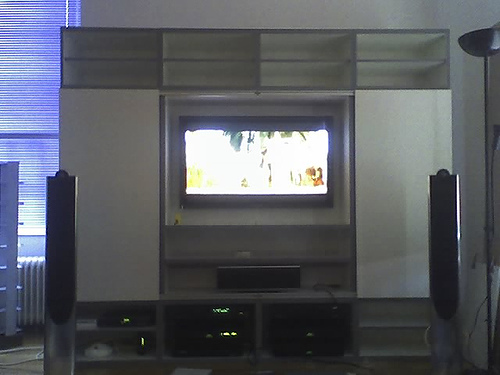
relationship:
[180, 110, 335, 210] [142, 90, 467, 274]
electronic built into wall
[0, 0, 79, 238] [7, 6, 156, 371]
shade are on wall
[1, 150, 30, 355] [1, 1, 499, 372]
object in living room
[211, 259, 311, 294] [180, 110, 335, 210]
speaker under electronic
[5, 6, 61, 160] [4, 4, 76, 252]
venetian blinds covering window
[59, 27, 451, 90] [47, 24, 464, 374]
shelf space on entertainment center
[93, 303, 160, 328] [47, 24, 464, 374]
electronic on entertainment center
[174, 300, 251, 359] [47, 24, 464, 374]
electronic on entertainment center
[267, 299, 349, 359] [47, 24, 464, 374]
electronic on entertainment center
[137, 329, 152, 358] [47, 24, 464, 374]
electronic on entertainment center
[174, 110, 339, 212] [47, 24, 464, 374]
electronic on entertainment center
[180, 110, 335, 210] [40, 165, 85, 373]
electronic has speaker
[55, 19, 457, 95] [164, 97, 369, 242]
shelves are above tv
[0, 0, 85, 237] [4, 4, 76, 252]
venetian blinds are on window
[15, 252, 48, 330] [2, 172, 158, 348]
radiator near wall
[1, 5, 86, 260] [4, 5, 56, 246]
window with a shade